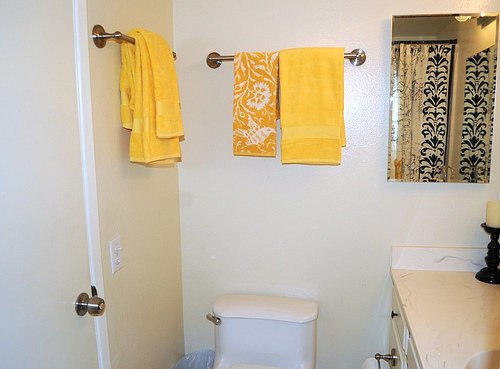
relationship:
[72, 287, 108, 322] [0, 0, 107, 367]
doorknob on a door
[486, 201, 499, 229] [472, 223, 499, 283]
candle in a holder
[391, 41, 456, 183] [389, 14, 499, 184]
curtain in mirror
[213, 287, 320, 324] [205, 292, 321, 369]
cover for toilet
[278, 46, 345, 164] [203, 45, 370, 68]
towel on rack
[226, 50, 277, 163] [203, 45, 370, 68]
towel on rack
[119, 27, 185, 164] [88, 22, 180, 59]
handtowel on rack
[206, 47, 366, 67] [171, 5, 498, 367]
metal bar on wall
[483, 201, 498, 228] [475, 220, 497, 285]
candle on candle holder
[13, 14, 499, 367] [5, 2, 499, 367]
picture in bathroom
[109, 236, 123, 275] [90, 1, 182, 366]
light switches on wall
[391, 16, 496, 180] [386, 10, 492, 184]
reflection on mirror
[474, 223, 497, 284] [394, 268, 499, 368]
stand on counter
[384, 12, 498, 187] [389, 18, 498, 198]
medicine chest reflects shower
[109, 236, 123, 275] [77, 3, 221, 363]
light switches on wall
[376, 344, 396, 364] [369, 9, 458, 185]
handle on cupboard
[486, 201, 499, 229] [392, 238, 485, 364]
candle on sink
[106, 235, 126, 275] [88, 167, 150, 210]
light switches on wall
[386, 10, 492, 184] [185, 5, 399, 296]
mirror hanging in wall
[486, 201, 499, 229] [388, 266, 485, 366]
candle on counter